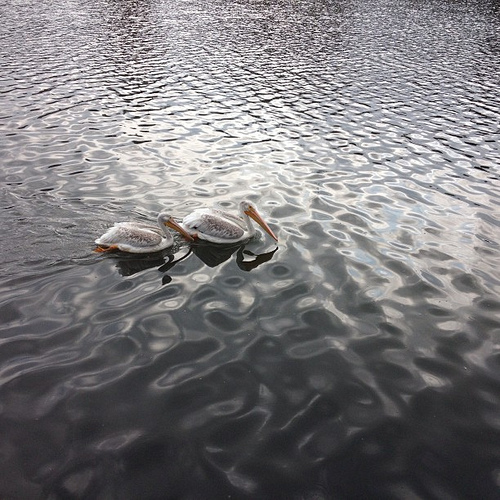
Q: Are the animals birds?
A: Yes, all the animals are birds.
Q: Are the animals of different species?
A: No, all the animals are birds.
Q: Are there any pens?
A: No, there are no pens.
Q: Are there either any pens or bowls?
A: No, there are no pens or bowls.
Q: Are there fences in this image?
A: No, there are no fences.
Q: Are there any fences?
A: No, there are no fences.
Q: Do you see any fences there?
A: No, there are no fences.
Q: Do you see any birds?
A: Yes, there is a bird.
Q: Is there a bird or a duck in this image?
A: Yes, there is a bird.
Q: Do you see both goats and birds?
A: No, there is a bird but no goats.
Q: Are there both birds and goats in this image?
A: No, there is a bird but no goats.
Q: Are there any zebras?
A: No, there are no zebras.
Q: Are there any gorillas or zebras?
A: No, there are no zebras or gorillas.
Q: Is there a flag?
A: No, there are no flags.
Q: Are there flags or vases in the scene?
A: No, there are no flags or vases.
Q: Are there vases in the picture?
A: No, there are no vases.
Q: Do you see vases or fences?
A: No, there are no vases or fences.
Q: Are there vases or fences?
A: No, there are no vases or fences.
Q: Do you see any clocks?
A: No, there are no clocks.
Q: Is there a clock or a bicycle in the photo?
A: No, there are no clocks or bicycles.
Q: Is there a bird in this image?
A: Yes, there is a bird.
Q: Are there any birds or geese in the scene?
A: Yes, there is a bird.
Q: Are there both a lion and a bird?
A: No, there is a bird but no lions.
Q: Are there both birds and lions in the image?
A: No, there is a bird but no lions.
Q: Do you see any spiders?
A: No, there are no spiders.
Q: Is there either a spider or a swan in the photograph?
A: No, there are no spiders or swans.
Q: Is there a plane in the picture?
A: No, there are no airplanes.